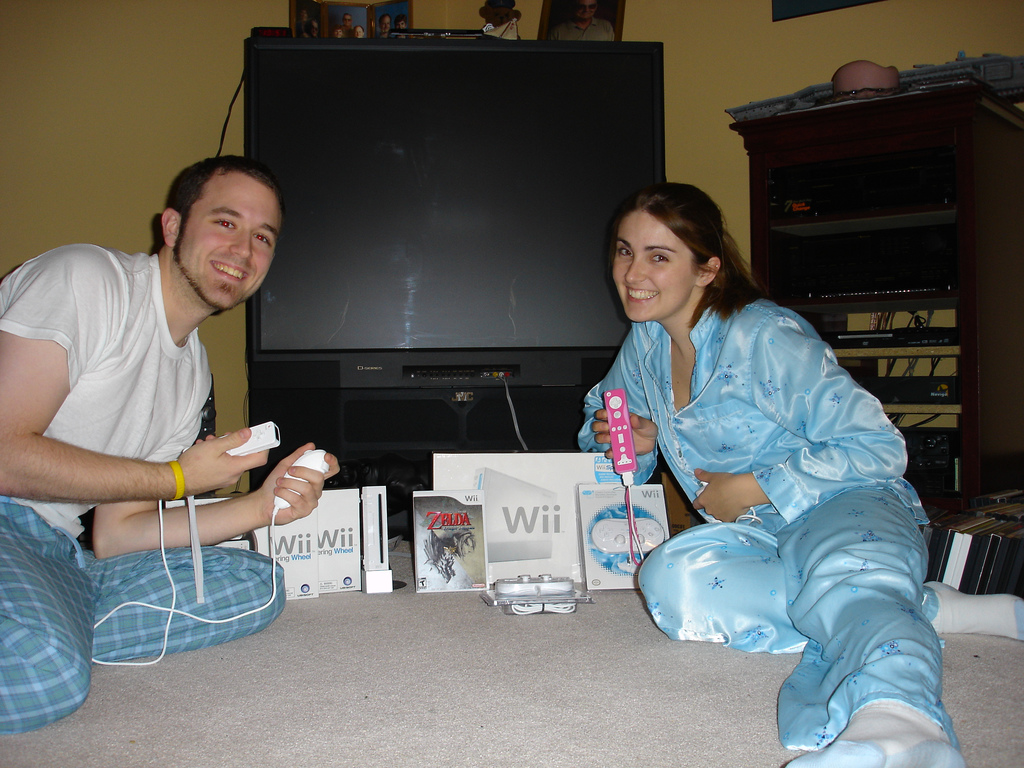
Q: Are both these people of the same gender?
A: No, they are both male and female.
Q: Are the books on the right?
A: Yes, the books are on the right of the image.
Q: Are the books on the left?
A: No, the books are on the right of the image.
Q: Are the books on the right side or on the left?
A: The books are on the right of the image.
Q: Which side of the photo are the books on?
A: The books are on the right of the image.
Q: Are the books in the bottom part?
A: Yes, the books are in the bottom of the image.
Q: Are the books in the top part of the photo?
A: No, the books are in the bottom of the image.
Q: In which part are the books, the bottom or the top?
A: The books are in the bottom of the image.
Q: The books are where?
A: The books are on the floor.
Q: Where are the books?
A: The books are on the floor.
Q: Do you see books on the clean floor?
A: Yes, there are books on the floor.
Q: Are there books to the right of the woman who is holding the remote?
A: Yes, there are books to the right of the woman.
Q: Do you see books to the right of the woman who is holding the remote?
A: Yes, there are books to the right of the woman.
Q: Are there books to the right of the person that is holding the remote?
A: Yes, there are books to the right of the woman.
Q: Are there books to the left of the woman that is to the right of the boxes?
A: No, the books are to the right of the woman.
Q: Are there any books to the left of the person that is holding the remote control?
A: No, the books are to the right of the woman.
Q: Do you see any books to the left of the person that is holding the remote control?
A: No, the books are to the right of the woman.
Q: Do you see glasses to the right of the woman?
A: No, there are books to the right of the woman.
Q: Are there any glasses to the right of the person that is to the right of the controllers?
A: No, there are books to the right of the woman.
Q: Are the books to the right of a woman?
A: Yes, the books are to the right of a woman.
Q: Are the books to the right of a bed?
A: No, the books are to the right of a woman.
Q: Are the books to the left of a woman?
A: No, the books are to the right of a woman.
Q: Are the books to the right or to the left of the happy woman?
A: The books are to the right of the woman.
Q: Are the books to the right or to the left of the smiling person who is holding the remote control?
A: The books are to the right of the woman.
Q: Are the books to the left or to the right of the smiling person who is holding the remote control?
A: The books are to the right of the woman.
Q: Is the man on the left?
A: Yes, the man is on the left of the image.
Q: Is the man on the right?
A: No, the man is on the left of the image.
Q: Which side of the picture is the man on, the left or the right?
A: The man is on the left of the image.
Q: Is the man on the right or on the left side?
A: The man is on the left of the image.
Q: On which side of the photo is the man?
A: The man is on the left of the image.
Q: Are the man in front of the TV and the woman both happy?
A: Yes, both the man and the woman are happy.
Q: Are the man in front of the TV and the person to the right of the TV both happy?
A: Yes, both the man and the woman are happy.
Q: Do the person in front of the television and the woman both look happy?
A: Yes, both the man and the woman are happy.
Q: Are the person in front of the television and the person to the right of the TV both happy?
A: Yes, both the man and the woman are happy.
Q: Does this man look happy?
A: Yes, the man is happy.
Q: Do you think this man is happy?
A: Yes, the man is happy.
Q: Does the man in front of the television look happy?
A: Yes, the man is happy.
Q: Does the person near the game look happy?
A: Yes, the man is happy.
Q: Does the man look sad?
A: No, the man is happy.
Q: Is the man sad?
A: No, the man is happy.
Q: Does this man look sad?
A: No, the man is happy.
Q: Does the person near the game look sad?
A: No, the man is happy.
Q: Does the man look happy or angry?
A: The man is happy.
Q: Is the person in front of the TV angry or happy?
A: The man is happy.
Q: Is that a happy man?
A: Yes, that is a happy man.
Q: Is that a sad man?
A: No, that is a happy man.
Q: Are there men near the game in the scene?
A: Yes, there is a man near the game.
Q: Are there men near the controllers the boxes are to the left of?
A: Yes, there is a man near the controllers.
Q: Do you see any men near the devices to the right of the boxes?
A: Yes, there is a man near the controllers.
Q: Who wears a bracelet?
A: The man wears a bracelet.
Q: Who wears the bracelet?
A: The man wears a bracelet.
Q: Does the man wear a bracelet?
A: Yes, the man wears a bracelet.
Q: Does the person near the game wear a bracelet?
A: Yes, the man wears a bracelet.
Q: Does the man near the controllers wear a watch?
A: No, the man wears a bracelet.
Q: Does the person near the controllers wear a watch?
A: No, the man wears a bracelet.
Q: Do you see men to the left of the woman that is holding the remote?
A: Yes, there is a man to the left of the woman.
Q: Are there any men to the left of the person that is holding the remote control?
A: Yes, there is a man to the left of the woman.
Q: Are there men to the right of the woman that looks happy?
A: No, the man is to the left of the woman.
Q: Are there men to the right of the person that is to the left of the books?
A: No, the man is to the left of the woman.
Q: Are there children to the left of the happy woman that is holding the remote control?
A: No, there is a man to the left of the woman.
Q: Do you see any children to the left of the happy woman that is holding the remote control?
A: No, there is a man to the left of the woman.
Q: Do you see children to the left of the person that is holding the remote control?
A: No, there is a man to the left of the woman.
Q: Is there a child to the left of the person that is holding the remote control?
A: No, there is a man to the left of the woman.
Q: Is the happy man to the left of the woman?
A: Yes, the man is to the left of the woman.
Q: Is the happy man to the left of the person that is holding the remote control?
A: Yes, the man is to the left of the woman.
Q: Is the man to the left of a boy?
A: No, the man is to the left of the woman.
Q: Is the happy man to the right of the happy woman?
A: No, the man is to the left of the woman.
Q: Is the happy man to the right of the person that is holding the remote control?
A: No, the man is to the left of the woman.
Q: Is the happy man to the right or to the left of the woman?
A: The man is to the left of the woman.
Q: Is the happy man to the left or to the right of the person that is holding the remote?
A: The man is to the left of the woman.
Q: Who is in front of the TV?
A: The man is in front of the TV.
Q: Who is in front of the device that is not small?
A: The man is in front of the TV.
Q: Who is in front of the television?
A: The man is in front of the TV.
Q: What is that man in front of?
A: The man is in front of the television.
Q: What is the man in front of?
A: The man is in front of the television.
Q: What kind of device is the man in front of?
A: The man is in front of the television.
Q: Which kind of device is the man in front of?
A: The man is in front of the television.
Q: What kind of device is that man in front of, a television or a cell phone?
A: The man is in front of a television.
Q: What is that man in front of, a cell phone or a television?
A: The man is in front of a television.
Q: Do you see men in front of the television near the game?
A: Yes, there is a man in front of the television.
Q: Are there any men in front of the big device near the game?
A: Yes, there is a man in front of the television.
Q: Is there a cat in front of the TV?
A: No, there is a man in front of the TV.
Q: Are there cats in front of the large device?
A: No, there is a man in front of the TV.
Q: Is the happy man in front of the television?
A: Yes, the man is in front of the television.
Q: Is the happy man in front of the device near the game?
A: Yes, the man is in front of the television.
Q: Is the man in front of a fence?
A: No, the man is in front of the television.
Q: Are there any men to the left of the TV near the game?
A: Yes, there is a man to the left of the TV.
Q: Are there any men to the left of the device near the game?
A: Yes, there is a man to the left of the TV.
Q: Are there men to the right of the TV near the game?
A: No, the man is to the left of the television.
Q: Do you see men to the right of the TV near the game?
A: No, the man is to the left of the television.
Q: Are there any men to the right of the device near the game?
A: No, the man is to the left of the television.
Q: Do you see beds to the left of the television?
A: No, there is a man to the left of the television.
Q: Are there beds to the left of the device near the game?
A: No, there is a man to the left of the television.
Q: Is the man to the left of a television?
A: Yes, the man is to the left of a television.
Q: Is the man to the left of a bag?
A: No, the man is to the left of a television.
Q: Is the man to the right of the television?
A: No, the man is to the left of the television.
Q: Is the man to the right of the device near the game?
A: No, the man is to the left of the television.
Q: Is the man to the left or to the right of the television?
A: The man is to the left of the television.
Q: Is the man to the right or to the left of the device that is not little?
A: The man is to the left of the television.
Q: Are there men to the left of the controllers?
A: Yes, there is a man to the left of the controllers.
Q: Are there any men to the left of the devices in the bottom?
A: Yes, there is a man to the left of the controllers.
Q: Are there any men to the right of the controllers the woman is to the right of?
A: No, the man is to the left of the controllers.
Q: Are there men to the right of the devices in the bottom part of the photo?
A: No, the man is to the left of the controllers.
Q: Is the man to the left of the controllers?
A: Yes, the man is to the left of the controllers.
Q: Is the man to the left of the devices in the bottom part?
A: Yes, the man is to the left of the controllers.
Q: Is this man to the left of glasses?
A: No, the man is to the left of the controllers.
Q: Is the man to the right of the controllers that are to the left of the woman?
A: No, the man is to the left of the controllers.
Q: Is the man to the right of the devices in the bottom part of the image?
A: No, the man is to the left of the controllers.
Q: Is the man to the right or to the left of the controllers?
A: The man is to the left of the controllers.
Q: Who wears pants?
A: The man wears pants.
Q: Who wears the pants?
A: The man wears pants.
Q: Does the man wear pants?
A: Yes, the man wears pants.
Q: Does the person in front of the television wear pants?
A: Yes, the man wears pants.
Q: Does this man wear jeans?
A: No, the man wears pants.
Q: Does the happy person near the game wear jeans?
A: No, the man wears pants.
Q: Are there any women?
A: Yes, there is a woman.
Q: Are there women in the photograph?
A: Yes, there is a woman.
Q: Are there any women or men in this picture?
A: Yes, there is a woman.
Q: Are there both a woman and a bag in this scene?
A: No, there is a woman but no bags.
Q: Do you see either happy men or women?
A: Yes, there is a happy woman.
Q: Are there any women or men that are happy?
A: Yes, the woman is happy.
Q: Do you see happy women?
A: Yes, there is a happy woman.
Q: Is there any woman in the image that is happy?
A: Yes, there is a woman that is happy.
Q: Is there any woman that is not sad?
A: Yes, there is a happy woman.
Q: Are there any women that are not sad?
A: Yes, there is a happy woman.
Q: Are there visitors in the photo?
A: No, there are no visitors.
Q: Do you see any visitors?
A: No, there are no visitors.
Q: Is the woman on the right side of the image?
A: Yes, the woman is on the right of the image.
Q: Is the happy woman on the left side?
A: No, the woman is on the right of the image.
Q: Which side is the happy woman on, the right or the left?
A: The woman is on the right of the image.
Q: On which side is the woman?
A: The woman is on the right of the image.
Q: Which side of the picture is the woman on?
A: The woman is on the right of the image.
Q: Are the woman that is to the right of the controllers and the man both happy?
A: Yes, both the woman and the man are happy.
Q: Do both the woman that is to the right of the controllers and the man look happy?
A: Yes, both the woman and the man are happy.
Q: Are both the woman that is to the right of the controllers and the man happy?
A: Yes, both the woman and the man are happy.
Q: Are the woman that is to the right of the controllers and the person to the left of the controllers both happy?
A: Yes, both the woman and the man are happy.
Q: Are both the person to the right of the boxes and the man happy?
A: Yes, both the woman and the man are happy.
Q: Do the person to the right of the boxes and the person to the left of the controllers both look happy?
A: Yes, both the woman and the man are happy.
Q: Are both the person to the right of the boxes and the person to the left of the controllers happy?
A: Yes, both the woman and the man are happy.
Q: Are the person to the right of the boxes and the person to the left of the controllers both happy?
A: Yes, both the woman and the man are happy.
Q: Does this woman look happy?
A: Yes, the woman is happy.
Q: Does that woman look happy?
A: Yes, the woman is happy.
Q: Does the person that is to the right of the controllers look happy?
A: Yes, the woman is happy.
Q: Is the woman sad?
A: No, the woman is happy.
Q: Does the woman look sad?
A: No, the woman is happy.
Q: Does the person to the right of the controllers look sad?
A: No, the woman is happy.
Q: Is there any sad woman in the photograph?
A: No, there is a woman but she is happy.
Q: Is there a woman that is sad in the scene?
A: No, there is a woman but she is happy.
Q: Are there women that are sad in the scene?
A: No, there is a woman but she is happy.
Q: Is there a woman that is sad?
A: No, there is a woman but she is happy.